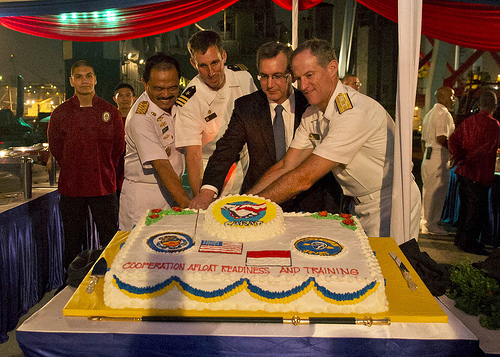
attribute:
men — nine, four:
[230, 35, 292, 196]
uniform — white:
[207, 105, 257, 165]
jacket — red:
[64, 142, 105, 178]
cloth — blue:
[58, 330, 85, 345]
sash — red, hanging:
[87, 1, 184, 32]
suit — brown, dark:
[287, 194, 308, 208]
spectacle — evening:
[0, 25, 144, 114]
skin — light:
[296, 59, 313, 67]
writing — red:
[201, 265, 223, 277]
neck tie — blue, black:
[269, 102, 280, 114]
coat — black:
[250, 147, 280, 165]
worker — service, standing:
[43, 53, 109, 222]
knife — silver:
[184, 203, 206, 212]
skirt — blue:
[14, 229, 47, 259]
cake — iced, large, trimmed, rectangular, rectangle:
[103, 208, 390, 315]